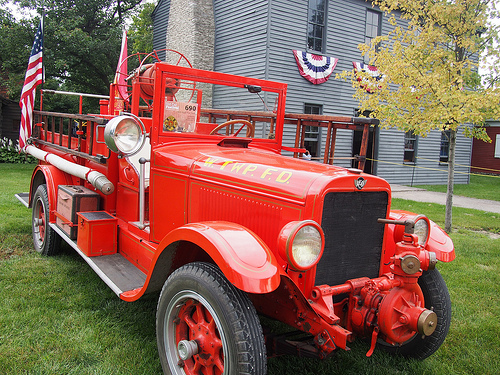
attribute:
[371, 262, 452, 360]
tire — black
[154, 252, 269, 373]
tire — black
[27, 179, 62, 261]
tire — black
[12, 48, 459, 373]
truck — red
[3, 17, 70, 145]
flag — American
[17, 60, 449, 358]
firetruck — old, red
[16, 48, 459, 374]
firetruck — red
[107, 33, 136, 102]
flag — red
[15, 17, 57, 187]
flag — American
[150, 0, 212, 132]
fire place — gray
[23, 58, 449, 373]
fire truck — old fashioned, red, antique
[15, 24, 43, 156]
flag — American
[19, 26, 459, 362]
fire truck — old, red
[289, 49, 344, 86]
cloth — red, white, blue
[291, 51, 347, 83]
banner — red, white, blue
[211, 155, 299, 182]
letters — yellow